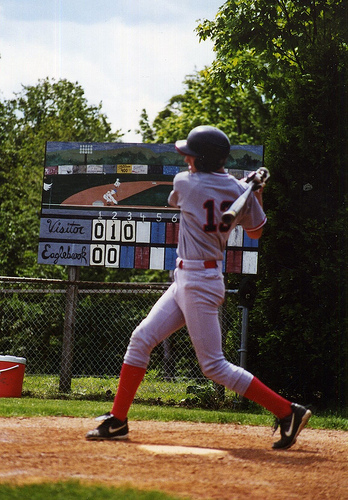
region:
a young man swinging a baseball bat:
[133, 109, 286, 372]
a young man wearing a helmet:
[165, 123, 237, 181]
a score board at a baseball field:
[33, 138, 278, 280]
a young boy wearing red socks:
[101, 356, 152, 442]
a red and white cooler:
[2, 339, 26, 412]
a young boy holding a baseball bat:
[210, 151, 265, 237]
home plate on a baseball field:
[120, 425, 231, 465]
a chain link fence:
[42, 273, 123, 392]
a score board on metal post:
[44, 200, 276, 404]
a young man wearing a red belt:
[179, 251, 225, 280]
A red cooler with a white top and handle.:
[0, 351, 28, 400]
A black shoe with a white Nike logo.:
[85, 411, 132, 445]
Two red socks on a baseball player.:
[105, 357, 295, 423]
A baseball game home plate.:
[132, 432, 234, 465]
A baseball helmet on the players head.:
[168, 119, 236, 176]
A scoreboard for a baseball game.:
[28, 131, 167, 278]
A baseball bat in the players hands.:
[215, 163, 273, 229]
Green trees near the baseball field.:
[265, 0, 344, 381]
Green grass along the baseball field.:
[3, 396, 102, 415]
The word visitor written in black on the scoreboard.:
[41, 215, 89, 238]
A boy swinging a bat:
[162, 157, 301, 444]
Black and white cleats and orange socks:
[231, 374, 311, 422]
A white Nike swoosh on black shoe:
[282, 412, 296, 445]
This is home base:
[134, 435, 236, 460]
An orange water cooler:
[2, 342, 36, 413]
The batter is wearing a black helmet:
[172, 122, 230, 169]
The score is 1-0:
[75, 197, 143, 269]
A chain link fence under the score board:
[14, 256, 111, 327]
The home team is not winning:
[39, 213, 138, 269]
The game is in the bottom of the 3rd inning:
[29, 210, 142, 271]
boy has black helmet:
[192, 115, 228, 167]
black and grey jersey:
[165, 182, 228, 264]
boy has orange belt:
[170, 258, 217, 280]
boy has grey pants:
[169, 279, 248, 377]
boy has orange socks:
[239, 371, 306, 416]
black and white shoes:
[283, 405, 326, 442]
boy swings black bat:
[188, 153, 260, 223]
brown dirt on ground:
[13, 410, 92, 483]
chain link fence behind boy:
[37, 290, 242, 388]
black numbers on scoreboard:
[84, 216, 142, 267]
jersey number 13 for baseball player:
[201, 197, 233, 235]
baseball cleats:
[84, 403, 312, 448]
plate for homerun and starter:
[133, 435, 225, 464]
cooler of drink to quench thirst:
[0, 351, 25, 399]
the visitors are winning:
[38, 215, 134, 266]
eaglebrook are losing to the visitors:
[39, 210, 133, 270]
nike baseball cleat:
[273, 405, 309, 449]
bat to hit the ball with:
[222, 168, 268, 229]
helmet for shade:
[173, 125, 230, 171]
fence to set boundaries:
[4, 276, 114, 399]